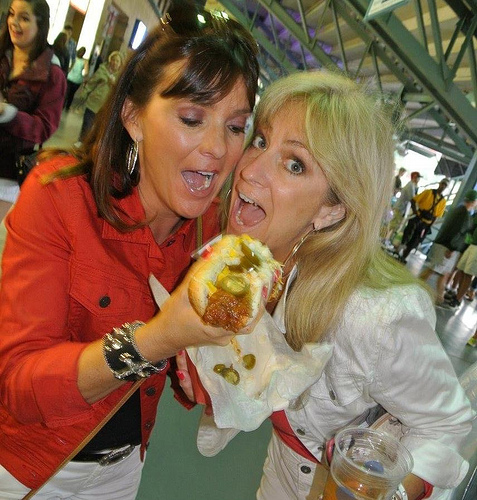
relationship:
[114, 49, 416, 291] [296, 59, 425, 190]
woman has blonde hair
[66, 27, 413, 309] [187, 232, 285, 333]
women have food